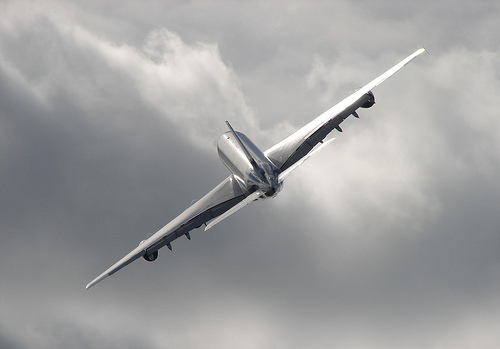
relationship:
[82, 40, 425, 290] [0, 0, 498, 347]
plane in sky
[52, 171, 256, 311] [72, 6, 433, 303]
wing on plane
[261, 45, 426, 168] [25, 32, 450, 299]
wing on plane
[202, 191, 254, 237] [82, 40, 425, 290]
wing on plane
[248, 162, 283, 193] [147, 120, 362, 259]
tail on plane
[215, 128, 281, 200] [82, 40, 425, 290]
body on plane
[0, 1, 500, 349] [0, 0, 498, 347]
cloud in sky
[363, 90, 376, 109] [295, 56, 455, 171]
black wheel on wing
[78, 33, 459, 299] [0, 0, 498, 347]
airplane flying in sky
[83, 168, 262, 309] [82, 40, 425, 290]
wing on plane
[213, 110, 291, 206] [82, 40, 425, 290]
tail on plane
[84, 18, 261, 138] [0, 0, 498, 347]
cloud in sky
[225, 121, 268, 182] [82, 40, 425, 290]
tail on plane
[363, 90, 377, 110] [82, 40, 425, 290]
black wheel on plane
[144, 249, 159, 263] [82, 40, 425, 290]
black wheel on plane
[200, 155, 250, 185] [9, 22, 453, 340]
shadow on plane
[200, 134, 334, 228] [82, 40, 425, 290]
back wings on plane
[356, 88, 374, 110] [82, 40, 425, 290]
turbines on plane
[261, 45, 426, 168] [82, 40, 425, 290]
wing on plane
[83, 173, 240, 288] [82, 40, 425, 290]
wing on plane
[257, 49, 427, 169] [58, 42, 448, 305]
right wing on plane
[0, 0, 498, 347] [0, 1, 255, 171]
sky full of clouds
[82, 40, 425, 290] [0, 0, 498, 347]
plane tilted in sky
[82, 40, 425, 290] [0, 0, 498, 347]
plane flying in sky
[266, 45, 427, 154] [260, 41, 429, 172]
light reflecting off plane wing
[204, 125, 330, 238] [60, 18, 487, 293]
tail on a plane